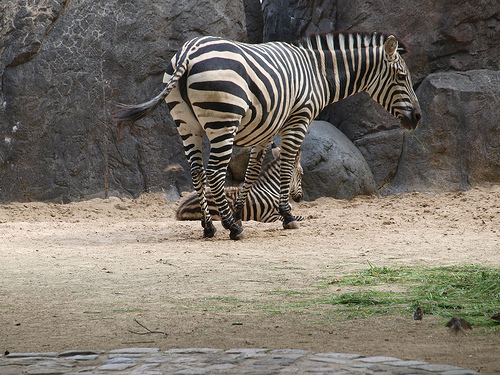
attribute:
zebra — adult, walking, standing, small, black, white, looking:
[131, 33, 421, 236]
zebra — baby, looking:
[174, 147, 309, 225]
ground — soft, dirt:
[3, 193, 497, 372]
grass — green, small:
[353, 261, 500, 318]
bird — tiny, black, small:
[414, 303, 424, 321]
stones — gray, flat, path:
[1, 346, 476, 374]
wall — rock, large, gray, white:
[3, 1, 500, 198]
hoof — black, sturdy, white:
[226, 226, 247, 241]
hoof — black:
[203, 227, 218, 237]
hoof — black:
[283, 218, 303, 235]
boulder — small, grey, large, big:
[423, 76, 499, 185]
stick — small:
[127, 319, 172, 344]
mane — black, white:
[292, 25, 406, 52]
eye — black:
[398, 69, 404, 84]